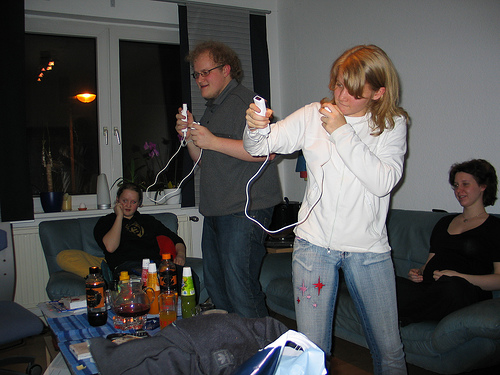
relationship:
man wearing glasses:
[174, 41, 282, 318] [191, 61, 229, 79]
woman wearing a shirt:
[241, 42, 410, 373] [242, 101, 408, 253]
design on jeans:
[296, 276, 326, 308] [292, 234, 408, 374]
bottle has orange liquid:
[145, 262, 161, 315] [145, 291, 162, 316]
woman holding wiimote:
[241, 42, 410, 373] [252, 95, 272, 139]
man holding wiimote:
[174, 41, 282, 318] [180, 102, 188, 137]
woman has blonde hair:
[241, 42, 410, 373] [320, 44, 411, 137]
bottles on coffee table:
[85, 252, 197, 327] [38, 289, 330, 374]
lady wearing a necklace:
[397, 158, 499, 326] [460, 210, 487, 221]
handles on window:
[101, 126, 123, 145] [25, 10, 194, 214]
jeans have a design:
[292, 234, 408, 374] [296, 276, 326, 308]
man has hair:
[174, 41, 282, 318] [185, 39, 244, 83]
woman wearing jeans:
[241, 42, 410, 373] [292, 234, 408, 374]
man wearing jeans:
[174, 41, 282, 318] [201, 203, 275, 318]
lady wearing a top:
[397, 158, 499, 326] [422, 214, 499, 281]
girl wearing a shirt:
[93, 182, 201, 307] [93, 209, 186, 272]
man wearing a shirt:
[174, 41, 282, 318] [199, 76, 284, 216]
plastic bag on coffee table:
[230, 329, 329, 374] [38, 289, 330, 374]